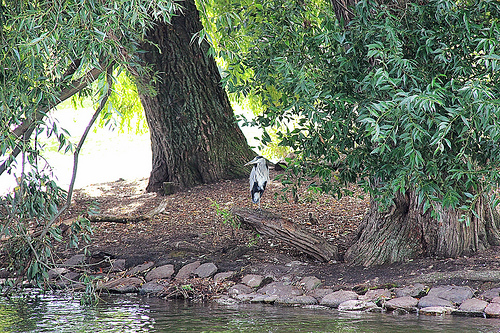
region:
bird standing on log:
[240, 154, 270, 209]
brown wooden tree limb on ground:
[231, 201, 343, 266]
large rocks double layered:
[3, 254, 498, 318]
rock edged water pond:
[1, 283, 499, 332]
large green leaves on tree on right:
[191, 9, 497, 228]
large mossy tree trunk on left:
[121, 0, 282, 194]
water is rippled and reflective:
[0, 285, 497, 330]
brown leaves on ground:
[2, 168, 498, 284]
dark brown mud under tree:
[104, 235, 497, 287]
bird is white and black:
[243, 152, 270, 212]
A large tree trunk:
[110, 4, 275, 189]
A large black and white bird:
[243, 155, 270, 208]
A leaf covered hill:
[83, 162, 365, 239]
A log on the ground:
[237, 205, 331, 263]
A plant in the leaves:
[209, 198, 252, 245]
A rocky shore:
[51, 255, 498, 317]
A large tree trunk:
[331, 0, 497, 261]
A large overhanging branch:
[0, 3, 170, 304]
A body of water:
[1, 281, 498, 331]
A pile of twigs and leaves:
[157, 273, 216, 303]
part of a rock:
[222, 278, 234, 298]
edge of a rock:
[312, 292, 322, 299]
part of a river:
[228, 306, 237, 316]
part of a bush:
[355, 125, 375, 157]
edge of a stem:
[218, 127, 232, 152]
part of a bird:
[256, 186, 258, 193]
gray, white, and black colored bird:
[244, 153, 267, 212]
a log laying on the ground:
[232, 205, 334, 260]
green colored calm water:
[1, 284, 498, 331]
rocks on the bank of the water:
[33, 252, 499, 319]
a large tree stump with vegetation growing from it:
[321, 22, 496, 271]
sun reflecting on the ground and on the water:
[2, 68, 148, 218]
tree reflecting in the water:
[0, 283, 52, 332]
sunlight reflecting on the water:
[39, 290, 154, 331]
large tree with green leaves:
[1, 1, 289, 194]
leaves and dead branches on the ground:
[67, 178, 359, 256]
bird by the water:
[236, 150, 277, 217]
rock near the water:
[187, 258, 220, 279]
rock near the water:
[237, 266, 269, 291]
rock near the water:
[222, 280, 253, 302]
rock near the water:
[292, 273, 323, 291]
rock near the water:
[315, 284, 362, 309]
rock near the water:
[336, 293, 381, 316]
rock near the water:
[375, 291, 421, 317]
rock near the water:
[450, 294, 490, 321]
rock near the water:
[120, 255, 158, 280]